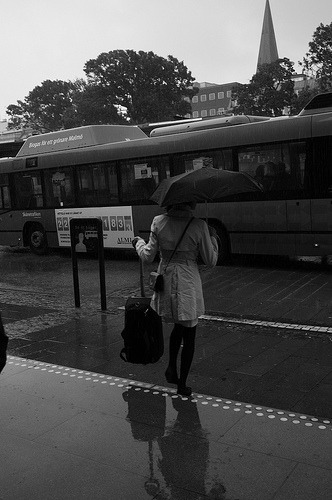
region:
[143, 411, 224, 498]
there is reflection on the ground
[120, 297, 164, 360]
the bag is black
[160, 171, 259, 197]
the umbrella is black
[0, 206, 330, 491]
it is raining in the photo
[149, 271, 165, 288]
the purse is black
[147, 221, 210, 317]
the coat is wrinkled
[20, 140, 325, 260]
the bus has passengers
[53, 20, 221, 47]
the sky is cloudy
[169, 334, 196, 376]
the stockings are black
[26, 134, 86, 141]
the writing is black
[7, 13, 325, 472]
A black and white rainy day scene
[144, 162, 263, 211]
A black umbrella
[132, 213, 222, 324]
A light colored rain coat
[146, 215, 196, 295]
A dark over the shoulder purse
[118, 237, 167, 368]
A rolling suitcase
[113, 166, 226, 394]
A women in black leggins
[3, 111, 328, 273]
A bus with people inside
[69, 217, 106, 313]
A sign indicating a bus stop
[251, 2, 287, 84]
A building steeple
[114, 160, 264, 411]
A woman crossing the street in the rain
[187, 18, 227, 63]
part of the sky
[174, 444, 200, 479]
part of a shade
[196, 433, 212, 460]
edge of a shade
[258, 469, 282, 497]
part of a floor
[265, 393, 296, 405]
edge of a road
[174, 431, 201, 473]
part of a shade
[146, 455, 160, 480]
part of a handle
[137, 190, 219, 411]
Woman standing in the rain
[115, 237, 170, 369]
Carry on luggage with extended handle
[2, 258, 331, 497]
Wet sidewalk plaza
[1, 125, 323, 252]
City bus with large windows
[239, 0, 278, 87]
Tall pyramidal church steeple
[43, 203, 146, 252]
Print advertisement with numbers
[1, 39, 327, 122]
Large full leaved trees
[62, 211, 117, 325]
Sign advertising bus stop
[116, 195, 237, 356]
Light colored rain coat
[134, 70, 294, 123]
Apartment building with rectangle windows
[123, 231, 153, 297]
handle of black suitcase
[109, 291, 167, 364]
black luggage on ground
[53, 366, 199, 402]
white circular stones on ground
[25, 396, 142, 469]
black tiles on the ground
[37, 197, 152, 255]
large sign on side of bus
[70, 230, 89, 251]
person on black sign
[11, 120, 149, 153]
large hump on top of bus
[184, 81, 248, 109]
windows in large building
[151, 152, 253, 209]
large spines in black umbrella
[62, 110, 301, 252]
large passenger bus